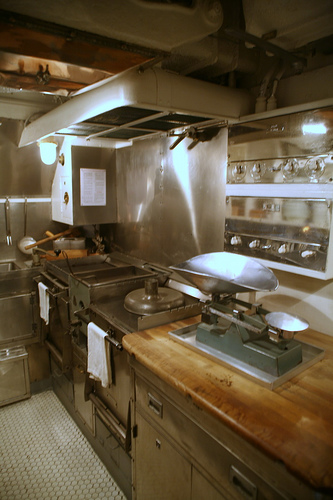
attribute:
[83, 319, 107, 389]
towel — white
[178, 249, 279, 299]
bed — scale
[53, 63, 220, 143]
range — kitchen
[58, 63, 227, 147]
hood — kitchen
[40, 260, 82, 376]
stove — kitchen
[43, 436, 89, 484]
floor — kitchen, dirty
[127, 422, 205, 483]
cabinet — kitchen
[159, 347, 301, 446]
counter — wood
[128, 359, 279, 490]
cabinet — wooden, old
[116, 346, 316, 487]
cabinet — cutting board, wooden, light brown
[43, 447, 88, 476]
floor — white, tile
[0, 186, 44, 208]
wall — back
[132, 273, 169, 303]
lid — silver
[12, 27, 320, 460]
kitchen — industrial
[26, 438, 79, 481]
floor — white, tile, kitchen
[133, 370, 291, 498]
drawer — stainless steel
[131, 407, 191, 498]
door — stainless steel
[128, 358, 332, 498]
cabinet — stainless steel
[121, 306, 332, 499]
counter top — wood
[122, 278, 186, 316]
lid — round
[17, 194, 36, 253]
ladle — large, industrial size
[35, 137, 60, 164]
light fixture — glass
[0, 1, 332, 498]
kitchen — cluttered, clean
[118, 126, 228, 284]
back — metal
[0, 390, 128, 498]
floor — dirty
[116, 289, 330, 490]
counter top — wooden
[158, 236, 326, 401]
scales — baby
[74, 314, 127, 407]
towel — white 